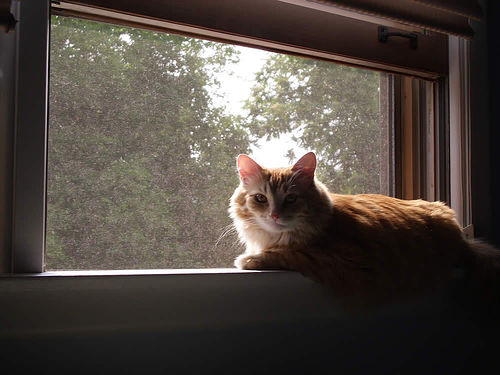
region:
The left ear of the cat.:
[232, 147, 264, 180]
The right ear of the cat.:
[288, 152, 320, 174]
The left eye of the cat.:
[242, 185, 270, 206]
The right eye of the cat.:
[277, 189, 302, 204]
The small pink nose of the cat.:
[266, 210, 279, 220]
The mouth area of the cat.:
[260, 219, 285, 231]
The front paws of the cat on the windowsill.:
[227, 253, 280, 270]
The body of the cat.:
[332, 183, 462, 293]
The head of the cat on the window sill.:
[229, 147, 319, 233]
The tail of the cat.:
[467, 233, 499, 300]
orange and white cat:
[226, 147, 499, 304]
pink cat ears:
[230, 149, 324, 183]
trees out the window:
[44, 16, 396, 274]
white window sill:
[24, 266, 357, 320]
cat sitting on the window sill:
[38, 149, 493, 297]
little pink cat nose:
[269, 212, 279, 219]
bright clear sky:
[183, 27, 319, 167]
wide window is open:
[20, 12, 458, 278]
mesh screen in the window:
[43, 15, 401, 270]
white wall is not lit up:
[0, 275, 490, 372]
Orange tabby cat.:
[218, 133, 485, 298]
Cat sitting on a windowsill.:
[210, 150, 490, 325]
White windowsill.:
[36, 260, 239, 327]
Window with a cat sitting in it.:
[11, 1, 495, 311]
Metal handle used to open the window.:
[370, 13, 427, 58]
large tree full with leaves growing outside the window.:
[55, 20, 218, 272]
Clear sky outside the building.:
[215, 53, 261, 118]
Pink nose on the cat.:
[265, 210, 283, 224]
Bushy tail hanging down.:
[459, 222, 498, 307]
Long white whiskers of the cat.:
[209, 211, 274, 248]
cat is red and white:
[234, 155, 485, 290]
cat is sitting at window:
[41, 4, 396, 253]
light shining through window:
[43, 4, 400, 280]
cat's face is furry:
[224, 166, 329, 245]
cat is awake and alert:
[229, 163, 328, 240]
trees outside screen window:
[59, 22, 250, 274]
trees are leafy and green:
[44, 29, 244, 264]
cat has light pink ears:
[225, 141, 323, 186]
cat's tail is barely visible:
[452, 213, 499, 305]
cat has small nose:
[266, 211, 291, 231]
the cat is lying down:
[221, 145, 489, 310]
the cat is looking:
[225, 153, 474, 305]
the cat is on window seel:
[218, 134, 475, 321]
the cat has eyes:
[244, 189, 302, 209]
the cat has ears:
[231, 145, 323, 184]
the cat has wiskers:
[216, 213, 267, 250]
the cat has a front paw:
[240, 250, 264, 273]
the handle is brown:
[370, 21, 427, 50]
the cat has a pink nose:
[266, 209, 284, 226]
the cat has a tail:
[472, 229, 493, 279]